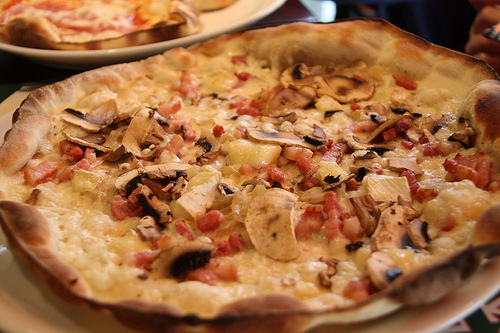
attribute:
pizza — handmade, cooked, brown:
[32, 70, 487, 292]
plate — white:
[4, 7, 499, 332]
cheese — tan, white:
[157, 60, 262, 111]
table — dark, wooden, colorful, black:
[0, 55, 69, 115]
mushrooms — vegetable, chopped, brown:
[72, 109, 118, 153]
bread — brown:
[14, 82, 62, 129]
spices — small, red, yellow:
[232, 54, 261, 96]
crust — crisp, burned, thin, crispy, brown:
[168, 32, 481, 74]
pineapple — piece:
[214, 135, 283, 170]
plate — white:
[4, 6, 296, 64]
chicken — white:
[359, 174, 413, 206]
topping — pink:
[35, 159, 76, 191]